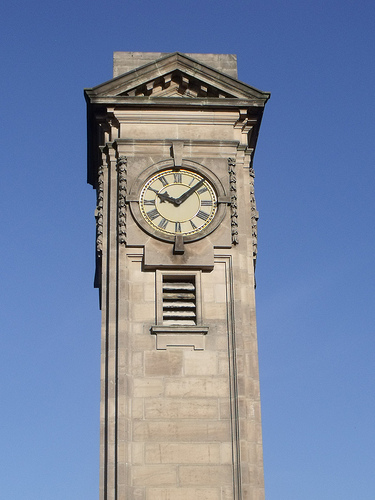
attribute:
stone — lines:
[164, 378, 228, 397]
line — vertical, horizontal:
[206, 417, 208, 441]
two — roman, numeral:
[197, 185, 210, 191]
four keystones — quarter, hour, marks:
[122, 133, 238, 265]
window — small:
[154, 267, 208, 329]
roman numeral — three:
[198, 198, 215, 208]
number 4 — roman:
[194, 207, 209, 222]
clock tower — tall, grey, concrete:
[82, 49, 272, 497]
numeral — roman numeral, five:
[163, 218, 188, 238]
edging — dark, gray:
[69, 34, 274, 122]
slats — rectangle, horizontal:
[152, 266, 204, 332]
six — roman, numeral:
[173, 220, 182, 230]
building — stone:
[80, 49, 272, 499]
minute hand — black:
[174, 174, 205, 205]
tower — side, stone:
[74, 35, 280, 498]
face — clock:
[137, 167, 220, 238]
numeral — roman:
[171, 172, 187, 186]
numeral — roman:
[155, 171, 172, 188]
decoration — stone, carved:
[223, 153, 244, 249]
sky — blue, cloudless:
[3, 0, 360, 498]